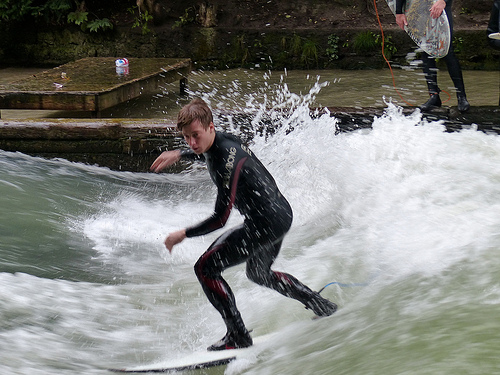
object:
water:
[0, 127, 500, 374]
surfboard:
[99, 331, 276, 372]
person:
[148, 95, 337, 350]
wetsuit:
[183, 131, 335, 349]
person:
[395, 0, 470, 112]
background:
[0, 1, 495, 171]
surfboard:
[384, 0, 449, 59]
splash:
[254, 73, 450, 160]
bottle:
[114, 59, 130, 73]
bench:
[1, 56, 191, 118]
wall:
[0, 0, 500, 66]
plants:
[43, 0, 132, 33]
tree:
[0, 0, 29, 23]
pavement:
[1, 69, 500, 128]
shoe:
[205, 331, 253, 350]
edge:
[110, 357, 232, 372]